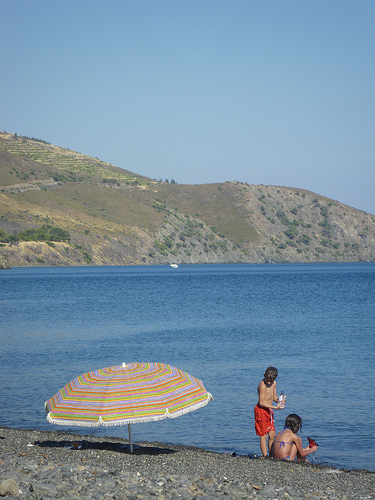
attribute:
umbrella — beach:
[32, 343, 224, 437]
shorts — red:
[253, 404, 276, 435]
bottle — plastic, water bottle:
[277, 393, 285, 405]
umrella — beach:
[43, 359, 216, 453]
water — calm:
[0, 266, 373, 366]